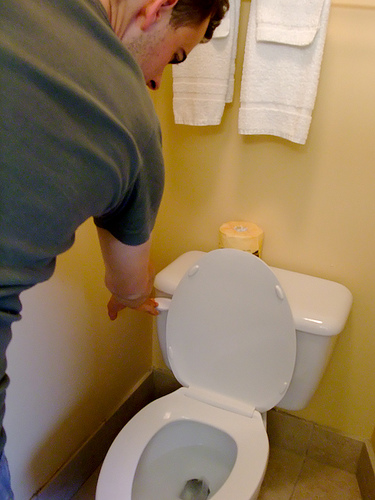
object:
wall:
[26, 5, 374, 443]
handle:
[142, 295, 172, 324]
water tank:
[153, 248, 353, 410]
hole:
[174, 477, 212, 498]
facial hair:
[136, 34, 149, 53]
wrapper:
[217, 220, 263, 259]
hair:
[172, 0, 231, 40]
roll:
[215, 214, 266, 260]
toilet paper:
[217, 219, 265, 262]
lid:
[164, 249, 296, 417]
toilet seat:
[97, 385, 268, 498]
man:
[0, 0, 228, 498]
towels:
[168, 0, 241, 132]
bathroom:
[0, 2, 373, 498]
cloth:
[236, 0, 326, 151]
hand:
[108, 289, 160, 321]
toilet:
[89, 245, 357, 498]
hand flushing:
[150, 294, 170, 312]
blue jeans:
[1, 443, 13, 499]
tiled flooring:
[80, 443, 360, 497]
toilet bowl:
[95, 244, 354, 498]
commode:
[153, 249, 354, 408]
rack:
[151, 22, 368, 311]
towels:
[236, 0, 329, 146]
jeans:
[0, 409, 17, 500]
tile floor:
[283, 447, 341, 488]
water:
[150, 445, 220, 494]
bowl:
[134, 408, 250, 498]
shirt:
[0, 6, 167, 466]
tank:
[150, 250, 349, 410]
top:
[158, 244, 303, 422]